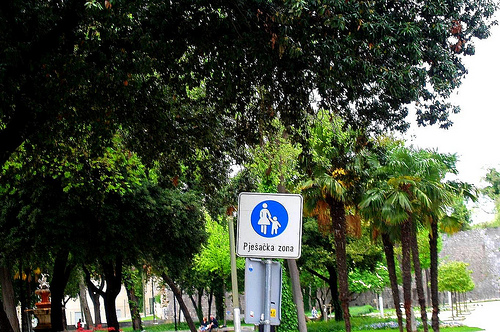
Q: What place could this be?
A: It is a park.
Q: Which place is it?
A: It is a park.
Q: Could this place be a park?
A: Yes, it is a park.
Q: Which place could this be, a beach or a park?
A: It is a park.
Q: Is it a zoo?
A: No, it is a park.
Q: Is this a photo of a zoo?
A: No, the picture is showing a park.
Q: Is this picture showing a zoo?
A: No, the picture is showing a park.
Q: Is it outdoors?
A: Yes, it is outdoors.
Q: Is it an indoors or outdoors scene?
A: It is outdoors.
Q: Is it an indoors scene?
A: No, it is outdoors.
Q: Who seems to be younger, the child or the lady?
A: The child is younger than the lady.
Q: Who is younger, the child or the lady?
A: The child is younger than the lady.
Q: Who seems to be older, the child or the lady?
A: The lady is older than the child.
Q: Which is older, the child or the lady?
A: The lady is older than the child.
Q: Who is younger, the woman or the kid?
A: The kid is younger than the woman.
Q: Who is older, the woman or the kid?
A: The woman is older than the kid.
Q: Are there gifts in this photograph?
A: No, there are no gifts.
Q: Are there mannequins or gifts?
A: No, there are no gifts or mannequins.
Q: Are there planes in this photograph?
A: No, there are no planes.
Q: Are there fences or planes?
A: No, there are no planes or fences.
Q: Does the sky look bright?
A: Yes, the sky is bright.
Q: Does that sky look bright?
A: Yes, the sky is bright.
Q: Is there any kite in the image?
A: No, there are no kites.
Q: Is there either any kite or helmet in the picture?
A: No, there are no kites or helmets.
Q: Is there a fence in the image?
A: No, there are no fences.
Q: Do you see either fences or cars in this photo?
A: No, there are no fences or cars.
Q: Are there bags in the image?
A: No, there are no bags.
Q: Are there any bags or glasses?
A: No, there are no bags or glasses.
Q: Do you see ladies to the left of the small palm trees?
A: Yes, there is a lady to the left of the palm trees.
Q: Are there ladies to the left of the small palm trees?
A: Yes, there is a lady to the left of the palm trees.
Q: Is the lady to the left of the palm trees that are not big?
A: Yes, the lady is to the left of the palms.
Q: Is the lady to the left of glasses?
A: No, the lady is to the left of the palms.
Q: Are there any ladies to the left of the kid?
A: Yes, there is a lady to the left of the kid.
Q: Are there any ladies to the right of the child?
A: No, the lady is to the left of the child.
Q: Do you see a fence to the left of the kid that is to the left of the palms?
A: No, there is a lady to the left of the kid.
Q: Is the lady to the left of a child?
A: Yes, the lady is to the left of a child.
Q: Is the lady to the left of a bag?
A: No, the lady is to the left of a child.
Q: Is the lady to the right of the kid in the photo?
A: No, the lady is to the left of the kid.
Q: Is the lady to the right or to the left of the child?
A: The lady is to the left of the child.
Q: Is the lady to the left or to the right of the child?
A: The lady is to the left of the child.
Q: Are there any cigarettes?
A: No, there are no cigarettes.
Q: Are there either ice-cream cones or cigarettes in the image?
A: No, there are no cigarettes or ice-cream cones.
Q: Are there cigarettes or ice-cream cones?
A: No, there are no cigarettes or ice-cream cones.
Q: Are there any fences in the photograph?
A: No, there are no fences.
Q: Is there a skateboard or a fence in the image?
A: No, there are no fences or skateboards.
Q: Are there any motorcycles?
A: No, there are no motorcycles.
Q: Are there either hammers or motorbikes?
A: No, there are no motorbikes or hammers.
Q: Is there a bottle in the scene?
A: No, there are no bottles.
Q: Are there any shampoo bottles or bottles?
A: No, there are no bottles or shampoo bottles.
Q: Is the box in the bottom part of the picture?
A: Yes, the box is in the bottom of the image.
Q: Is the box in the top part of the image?
A: No, the box is in the bottom of the image.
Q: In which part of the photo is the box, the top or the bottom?
A: The box is in the bottom of the image.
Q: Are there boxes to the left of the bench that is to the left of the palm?
A: Yes, there is a box to the left of the bench.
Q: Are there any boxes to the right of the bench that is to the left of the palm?
A: No, the box is to the left of the bench.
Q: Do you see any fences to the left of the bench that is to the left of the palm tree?
A: No, there is a box to the left of the bench.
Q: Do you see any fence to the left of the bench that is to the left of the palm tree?
A: No, there is a box to the left of the bench.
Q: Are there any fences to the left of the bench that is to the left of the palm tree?
A: No, there is a box to the left of the bench.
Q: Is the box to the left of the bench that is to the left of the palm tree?
A: Yes, the box is to the left of the bench.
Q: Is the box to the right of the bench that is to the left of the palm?
A: No, the box is to the left of the bench.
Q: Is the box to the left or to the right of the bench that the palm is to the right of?
A: The box is to the left of the bench.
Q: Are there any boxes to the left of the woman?
A: Yes, there is a box to the left of the woman.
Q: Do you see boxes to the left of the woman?
A: Yes, there is a box to the left of the woman.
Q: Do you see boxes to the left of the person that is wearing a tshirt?
A: Yes, there is a box to the left of the woman.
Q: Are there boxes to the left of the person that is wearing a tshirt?
A: Yes, there is a box to the left of the woman.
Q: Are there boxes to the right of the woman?
A: No, the box is to the left of the woman.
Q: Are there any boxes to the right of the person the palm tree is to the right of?
A: No, the box is to the left of the woman.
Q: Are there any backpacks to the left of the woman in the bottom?
A: No, there is a box to the left of the woman.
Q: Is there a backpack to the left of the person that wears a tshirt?
A: No, there is a box to the left of the woman.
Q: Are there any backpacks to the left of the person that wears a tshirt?
A: No, there is a box to the left of the woman.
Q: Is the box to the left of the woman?
A: Yes, the box is to the left of the woman.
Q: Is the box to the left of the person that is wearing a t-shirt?
A: Yes, the box is to the left of the woman.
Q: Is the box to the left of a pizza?
A: No, the box is to the left of the woman.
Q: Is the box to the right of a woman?
A: No, the box is to the left of a woman.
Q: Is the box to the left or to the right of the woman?
A: The box is to the left of the woman.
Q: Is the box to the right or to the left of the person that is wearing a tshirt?
A: The box is to the left of the woman.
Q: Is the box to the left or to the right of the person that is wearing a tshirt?
A: The box is to the left of the woman.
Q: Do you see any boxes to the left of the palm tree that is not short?
A: Yes, there is a box to the left of the palm tree.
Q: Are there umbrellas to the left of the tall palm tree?
A: No, there is a box to the left of the palm.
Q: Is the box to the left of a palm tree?
A: Yes, the box is to the left of a palm tree.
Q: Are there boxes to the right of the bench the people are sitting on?
A: Yes, there is a box to the right of the bench.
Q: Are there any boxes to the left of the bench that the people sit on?
A: No, the box is to the right of the bench.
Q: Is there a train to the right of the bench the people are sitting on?
A: No, there is a box to the right of the bench.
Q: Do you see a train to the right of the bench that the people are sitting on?
A: No, there is a box to the right of the bench.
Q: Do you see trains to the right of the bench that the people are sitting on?
A: No, there is a box to the right of the bench.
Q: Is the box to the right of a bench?
A: Yes, the box is to the right of a bench.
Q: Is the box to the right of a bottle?
A: No, the box is to the right of a bench.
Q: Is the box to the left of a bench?
A: No, the box is to the right of a bench.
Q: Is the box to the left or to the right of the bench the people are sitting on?
A: The box is to the right of the bench.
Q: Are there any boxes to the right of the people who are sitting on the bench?
A: Yes, there is a box to the right of the people.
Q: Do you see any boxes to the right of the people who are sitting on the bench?
A: Yes, there is a box to the right of the people.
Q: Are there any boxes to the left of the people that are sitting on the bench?
A: No, the box is to the right of the people.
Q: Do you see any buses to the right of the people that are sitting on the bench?
A: No, there is a box to the right of the people.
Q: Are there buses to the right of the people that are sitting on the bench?
A: No, there is a box to the right of the people.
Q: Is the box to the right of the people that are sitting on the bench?
A: Yes, the box is to the right of the people.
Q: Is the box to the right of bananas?
A: No, the box is to the right of the people.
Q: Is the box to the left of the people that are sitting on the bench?
A: No, the box is to the right of the people.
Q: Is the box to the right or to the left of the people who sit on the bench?
A: The box is to the right of the people.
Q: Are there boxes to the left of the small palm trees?
A: Yes, there is a box to the left of the palm trees.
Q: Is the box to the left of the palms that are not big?
A: Yes, the box is to the left of the palms.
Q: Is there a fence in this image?
A: No, there are no fences.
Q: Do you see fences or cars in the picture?
A: No, there are no fences or cars.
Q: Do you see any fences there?
A: No, there are no fences.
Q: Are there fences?
A: No, there are no fences.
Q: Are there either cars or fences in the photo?
A: No, there are no fences or cars.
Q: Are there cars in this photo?
A: No, there are no cars.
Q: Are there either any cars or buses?
A: No, there are no cars or buses.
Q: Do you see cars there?
A: No, there are no cars.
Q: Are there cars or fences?
A: No, there are no cars or fences.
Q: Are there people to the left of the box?
A: Yes, there are people to the left of the box.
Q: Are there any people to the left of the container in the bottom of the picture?
A: Yes, there are people to the left of the box.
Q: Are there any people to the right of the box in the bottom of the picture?
A: No, the people are to the left of the box.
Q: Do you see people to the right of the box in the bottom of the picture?
A: No, the people are to the left of the box.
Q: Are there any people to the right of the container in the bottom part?
A: No, the people are to the left of the box.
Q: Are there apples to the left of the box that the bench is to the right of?
A: No, there are people to the left of the box.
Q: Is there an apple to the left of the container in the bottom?
A: No, there are people to the left of the box.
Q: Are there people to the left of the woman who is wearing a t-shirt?
A: Yes, there are people to the left of the woman.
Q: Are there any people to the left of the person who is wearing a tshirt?
A: Yes, there are people to the left of the woman.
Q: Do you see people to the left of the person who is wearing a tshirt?
A: Yes, there are people to the left of the woman.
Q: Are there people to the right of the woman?
A: No, the people are to the left of the woman.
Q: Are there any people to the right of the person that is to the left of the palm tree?
A: No, the people are to the left of the woman.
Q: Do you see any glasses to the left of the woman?
A: No, there are people to the left of the woman.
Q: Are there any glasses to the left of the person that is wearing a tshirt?
A: No, there are people to the left of the woman.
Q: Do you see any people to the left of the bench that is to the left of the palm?
A: Yes, there are people to the left of the bench.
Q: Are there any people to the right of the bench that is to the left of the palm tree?
A: No, the people are to the left of the bench.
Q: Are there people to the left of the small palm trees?
A: Yes, there are people to the left of the palm trees.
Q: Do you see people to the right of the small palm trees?
A: No, the people are to the left of the palms.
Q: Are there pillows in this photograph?
A: No, there are no pillows.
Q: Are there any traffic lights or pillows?
A: No, there are no pillows or traffic lights.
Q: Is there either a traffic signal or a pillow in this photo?
A: No, there are no pillows or traffic lights.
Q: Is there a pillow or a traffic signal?
A: No, there are no pillows or traffic lights.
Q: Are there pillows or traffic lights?
A: No, there are no pillows or traffic lights.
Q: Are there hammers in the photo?
A: No, there are no hammers.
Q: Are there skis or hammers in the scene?
A: No, there are no hammers or skis.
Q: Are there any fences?
A: No, there are no fences.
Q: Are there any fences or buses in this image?
A: No, there are no fences or buses.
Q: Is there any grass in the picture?
A: Yes, there is grass.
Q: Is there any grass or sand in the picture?
A: Yes, there is grass.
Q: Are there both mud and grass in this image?
A: No, there is grass but no mud.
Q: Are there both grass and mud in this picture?
A: No, there is grass but no mud.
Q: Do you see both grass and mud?
A: No, there is grass but no mud.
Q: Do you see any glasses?
A: No, there are no glasses.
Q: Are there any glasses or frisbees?
A: No, there are no glasses or frisbees.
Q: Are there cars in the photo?
A: No, there are no cars.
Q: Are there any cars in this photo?
A: No, there are no cars.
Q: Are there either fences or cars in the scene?
A: No, there are no cars or fences.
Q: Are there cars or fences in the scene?
A: No, there are no cars or fences.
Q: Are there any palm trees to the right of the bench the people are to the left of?
A: Yes, there is a palm tree to the right of the bench.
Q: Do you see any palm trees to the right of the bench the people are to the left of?
A: Yes, there is a palm tree to the right of the bench.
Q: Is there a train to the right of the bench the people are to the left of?
A: No, there is a palm tree to the right of the bench.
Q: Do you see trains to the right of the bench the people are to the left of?
A: No, there is a palm tree to the right of the bench.